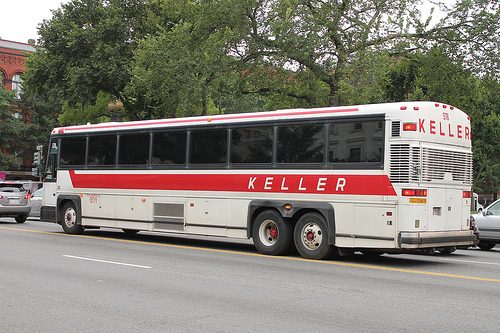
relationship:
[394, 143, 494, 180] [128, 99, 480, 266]
vents on bus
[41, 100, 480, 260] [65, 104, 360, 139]
bus with stripe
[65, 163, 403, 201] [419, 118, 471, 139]
red stripe with keller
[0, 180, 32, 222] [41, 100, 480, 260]
car in front of bus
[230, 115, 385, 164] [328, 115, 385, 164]
reflection on windows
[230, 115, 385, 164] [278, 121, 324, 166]
reflection on windows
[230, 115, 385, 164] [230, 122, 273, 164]
reflection on windows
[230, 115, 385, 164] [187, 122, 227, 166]
reflection on windows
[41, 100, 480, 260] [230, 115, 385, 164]
bus has reflection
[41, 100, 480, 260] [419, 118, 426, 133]
bus has k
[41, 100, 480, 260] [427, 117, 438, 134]
bus has red letter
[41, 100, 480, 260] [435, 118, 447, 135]
bus has red letter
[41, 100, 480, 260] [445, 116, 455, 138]
bus has red letter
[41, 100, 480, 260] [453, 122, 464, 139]
bus has red letter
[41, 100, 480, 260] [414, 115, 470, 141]
bus has keller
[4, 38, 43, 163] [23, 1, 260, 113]
brick building behind trees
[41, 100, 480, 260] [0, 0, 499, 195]
bus passes park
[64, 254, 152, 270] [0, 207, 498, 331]
line on pavement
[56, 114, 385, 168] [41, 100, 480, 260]
passenger windows on bus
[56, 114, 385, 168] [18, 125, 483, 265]
passenger windows on bus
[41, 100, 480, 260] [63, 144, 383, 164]
bus carrying passengers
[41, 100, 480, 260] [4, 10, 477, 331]
bus in city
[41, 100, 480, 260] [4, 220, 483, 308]
bus in route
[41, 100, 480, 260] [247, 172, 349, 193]
bus owned company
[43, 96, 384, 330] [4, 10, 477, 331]
bus operated city